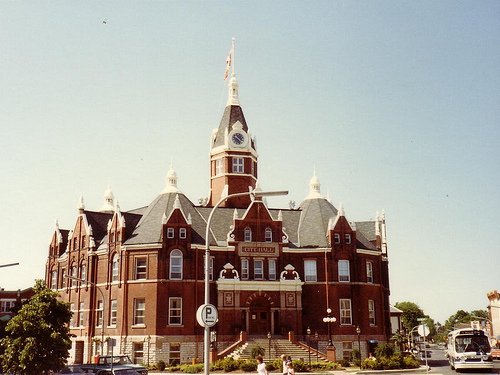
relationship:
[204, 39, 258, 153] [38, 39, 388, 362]
clock tower on building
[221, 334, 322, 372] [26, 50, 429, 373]
stairs leading to building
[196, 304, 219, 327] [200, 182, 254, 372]
sign on pole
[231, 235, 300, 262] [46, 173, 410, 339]
sign on front of building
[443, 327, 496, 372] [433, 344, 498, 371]
bus on road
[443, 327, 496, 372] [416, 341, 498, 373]
bus on road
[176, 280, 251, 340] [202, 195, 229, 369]
sign on pole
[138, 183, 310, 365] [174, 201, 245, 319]
light on pole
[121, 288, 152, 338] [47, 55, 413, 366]
window on building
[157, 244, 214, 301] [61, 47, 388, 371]
window on building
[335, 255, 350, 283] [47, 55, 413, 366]
window in a building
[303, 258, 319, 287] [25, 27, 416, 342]
window in a building